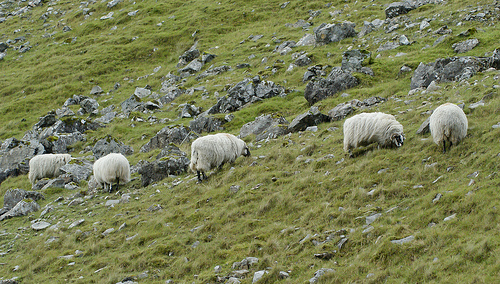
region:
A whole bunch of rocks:
[120, 54, 493, 96]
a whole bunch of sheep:
[24, 132, 499, 187]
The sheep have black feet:
[200, 170, 207, 185]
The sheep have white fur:
[207, 142, 237, 164]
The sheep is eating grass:
[394, 130, 411, 160]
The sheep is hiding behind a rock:
[43, 157, 80, 187]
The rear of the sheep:
[429, 105, 471, 162]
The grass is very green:
[282, 173, 342, 220]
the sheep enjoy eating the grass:
[190, 125, 264, 198]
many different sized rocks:
[134, 35, 289, 128]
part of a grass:
[386, 156, 441, 207]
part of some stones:
[311, 225, 344, 253]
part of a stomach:
[203, 130, 246, 157]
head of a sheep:
[383, 120, 413, 158]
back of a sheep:
[189, 143, 204, 168]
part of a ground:
[251, 182, 292, 229]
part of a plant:
[149, 147, 180, 182]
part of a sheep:
[333, 102, 370, 145]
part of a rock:
[237, 72, 266, 95]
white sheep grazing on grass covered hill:
[336, 110, 406, 157]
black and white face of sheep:
[386, 127, 406, 147]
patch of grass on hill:
[268, 188, 340, 219]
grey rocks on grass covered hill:
[175, 25, 215, 78]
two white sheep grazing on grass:
[12, 140, 134, 197]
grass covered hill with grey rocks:
[4, 2, 267, 122]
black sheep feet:
[188, 169, 210, 183]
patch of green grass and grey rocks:
[376, 218, 448, 265]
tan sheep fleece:
[355, 120, 384, 135]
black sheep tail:
[441, 124, 454, 139]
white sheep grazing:
[436, 100, 477, 150]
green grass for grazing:
[208, 186, 407, 251]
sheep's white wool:
[347, 119, 386, 131]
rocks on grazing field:
[52, 90, 203, 122]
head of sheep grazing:
[237, 140, 258, 160]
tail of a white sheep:
[116, 157, 140, 188]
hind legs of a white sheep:
[186, 165, 212, 182]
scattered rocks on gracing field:
[102, 26, 498, 98]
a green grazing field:
[7, 8, 494, 265]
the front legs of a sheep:
[221, 156, 238, 176]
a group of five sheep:
[25, 103, 486, 201]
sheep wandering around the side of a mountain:
[326, 81, 483, 184]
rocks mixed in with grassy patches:
[251, 23, 498, 87]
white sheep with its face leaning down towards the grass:
[177, 121, 258, 183]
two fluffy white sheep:
[338, 92, 477, 154]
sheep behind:
[431, 102, 466, 148]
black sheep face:
[239, 143, 255, 158]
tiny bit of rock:
[430, 187, 442, 205]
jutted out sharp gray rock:
[209, 66, 284, 117]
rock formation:
[0, 87, 186, 221]